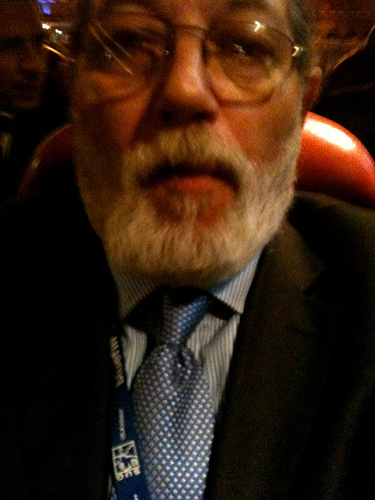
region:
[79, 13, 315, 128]
the eyes of a man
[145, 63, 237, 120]
the nose of a man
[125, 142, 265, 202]
the mouth of a man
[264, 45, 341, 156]
the ear of a man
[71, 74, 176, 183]
the cheek of a man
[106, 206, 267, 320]
the chin of a man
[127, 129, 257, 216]
the lips of a man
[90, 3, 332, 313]
the face of a man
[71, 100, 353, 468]
a man wearing a tie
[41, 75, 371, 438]
a man wearing a shirt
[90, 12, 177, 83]
this is an eye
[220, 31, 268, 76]
this is an eye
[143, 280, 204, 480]
this is a tie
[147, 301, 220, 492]
this is a blue and white tie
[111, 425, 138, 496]
this is a job tag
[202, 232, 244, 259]
this is white bead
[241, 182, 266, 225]
this is white bead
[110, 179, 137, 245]
this is white bead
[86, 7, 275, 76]
these are clear spectacles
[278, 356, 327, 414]
this is a black coat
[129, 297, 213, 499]
blue necktie with white dots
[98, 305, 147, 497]
a dark blue lanyard around neck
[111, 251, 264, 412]
a blue striped dress shirt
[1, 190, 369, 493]
a black suit coat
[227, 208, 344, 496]
a lapel with buttonhole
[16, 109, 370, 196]
top of a red chair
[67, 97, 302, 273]
a full white beard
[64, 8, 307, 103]
metal rimmed eyeglasses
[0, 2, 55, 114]
a person looking over a mans right shoulder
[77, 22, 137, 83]
a reflection of overhead lights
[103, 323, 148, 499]
the strap on the mans shirt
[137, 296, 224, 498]
the blue tie on the man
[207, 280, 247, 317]
the striped collar of the shirt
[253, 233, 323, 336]
the collar of the black jacket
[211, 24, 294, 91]
the lens of the glasses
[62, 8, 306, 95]
the glasses on the mans face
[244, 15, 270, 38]
thge light reflection in the lens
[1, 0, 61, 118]
the face behind the mans shoulder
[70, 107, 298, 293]
the white beard on the mans face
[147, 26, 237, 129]
nose of a person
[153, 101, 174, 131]
nostril of a person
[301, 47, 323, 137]
ear of a person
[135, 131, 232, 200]
mouth of a person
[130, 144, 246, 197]
lips of a person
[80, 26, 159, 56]
eye of a person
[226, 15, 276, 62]
eye of a person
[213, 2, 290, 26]
eye brow of a person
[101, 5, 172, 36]
eye brow of a person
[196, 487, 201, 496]
white dot on tie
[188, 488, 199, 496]
white dot on tie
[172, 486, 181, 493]
white dot on tie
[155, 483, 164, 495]
white dot on tie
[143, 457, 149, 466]
white dot on tie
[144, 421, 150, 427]
white dot on tie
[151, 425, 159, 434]
white dot on tie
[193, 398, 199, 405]
white dot on tie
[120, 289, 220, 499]
blue and silver necktie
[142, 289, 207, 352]
knot on a necktie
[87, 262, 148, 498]
blue and white lanyard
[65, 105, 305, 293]
man's white facial hair